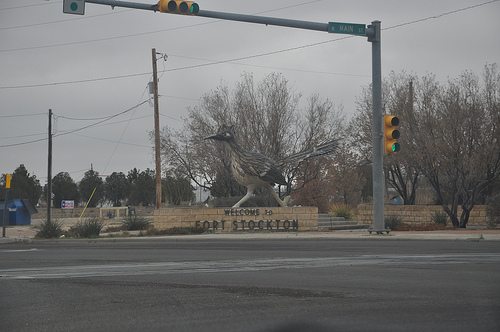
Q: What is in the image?
A: Bird statue.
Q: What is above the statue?
A: Power line.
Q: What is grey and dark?
A: The sky.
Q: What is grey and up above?
A: The sky.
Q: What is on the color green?
A: Two traffic lights.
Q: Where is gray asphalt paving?
A: At intersection.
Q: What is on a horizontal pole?
A: Traffic light.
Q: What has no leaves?
A: A tree.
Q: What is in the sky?
A: Cloud cover.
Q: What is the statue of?
A: A running bird.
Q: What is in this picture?
A: Giant bird.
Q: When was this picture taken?
A: During the day.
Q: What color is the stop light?
A: Green.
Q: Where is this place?
A: Fort Stockton.